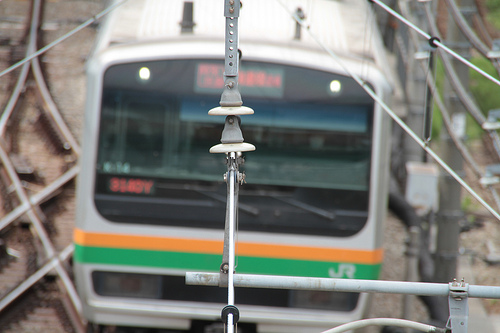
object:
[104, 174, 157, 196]
train/reader screen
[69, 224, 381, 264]
stripes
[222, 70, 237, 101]
silver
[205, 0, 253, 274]
apparatus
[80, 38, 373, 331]
front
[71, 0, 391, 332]
bus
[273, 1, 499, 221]
wires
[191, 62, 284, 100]
train name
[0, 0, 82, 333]
railroad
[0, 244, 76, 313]
crossing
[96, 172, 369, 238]
windshield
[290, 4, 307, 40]
exhaust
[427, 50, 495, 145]
grass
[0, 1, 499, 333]
station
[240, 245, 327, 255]
orange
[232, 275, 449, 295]
metal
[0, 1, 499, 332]
picture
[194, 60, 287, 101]
electronic sign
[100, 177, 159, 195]
electronic sign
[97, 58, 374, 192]
front window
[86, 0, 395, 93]
top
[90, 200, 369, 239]
edge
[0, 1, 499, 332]
ground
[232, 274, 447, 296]
steel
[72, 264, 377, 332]
bottom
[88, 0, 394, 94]
roof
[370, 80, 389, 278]
edge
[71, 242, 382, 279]
stripe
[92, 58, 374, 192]
windshield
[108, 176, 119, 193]
number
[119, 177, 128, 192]
number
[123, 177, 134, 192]
number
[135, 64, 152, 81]
light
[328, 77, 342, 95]
light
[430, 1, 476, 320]
telephone pole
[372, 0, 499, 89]
wire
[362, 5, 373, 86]
wire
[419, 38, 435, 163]
wire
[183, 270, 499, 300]
pole